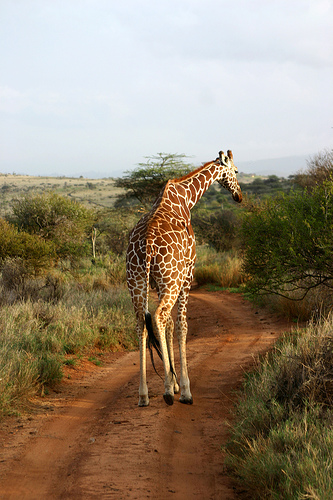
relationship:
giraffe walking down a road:
[126, 148, 242, 401] [139, 259, 294, 318]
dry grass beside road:
[221, 303, 332, 498] [35, 282, 272, 485]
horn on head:
[219, 150, 224, 157] [213, 144, 242, 199]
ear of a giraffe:
[222, 155, 229, 166] [123, 148, 244, 409]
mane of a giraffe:
[146, 160, 219, 225] [123, 148, 244, 409]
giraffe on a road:
[94, 138, 256, 406] [39, 289, 286, 493]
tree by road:
[237, 197, 332, 295] [2, 291, 273, 498]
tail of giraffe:
[139, 230, 156, 365] [126, 148, 242, 401]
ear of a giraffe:
[222, 143, 230, 168] [126, 148, 242, 401]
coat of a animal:
[115, 164, 216, 334] [117, 147, 253, 414]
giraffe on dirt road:
[126, 148, 242, 401] [62, 370, 205, 498]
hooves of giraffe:
[137, 393, 193, 409] [132, 143, 234, 405]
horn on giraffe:
[212, 141, 243, 166] [123, 148, 244, 409]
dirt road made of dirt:
[0, 285, 300, 500] [1, 278, 291, 498]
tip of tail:
[141, 310, 165, 377] [141, 254, 170, 381]